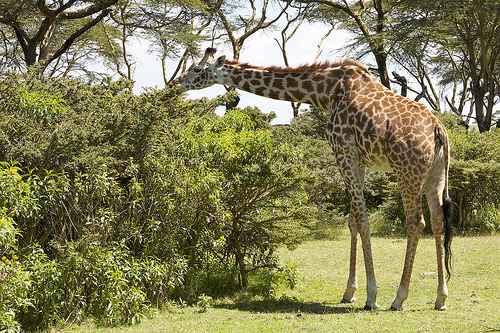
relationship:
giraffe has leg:
[170, 46, 454, 311] [340, 172, 384, 314]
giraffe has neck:
[170, 46, 454, 311] [216, 60, 335, 107]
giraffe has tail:
[170, 46, 454, 311] [435, 123, 456, 283]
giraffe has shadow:
[170, 46, 454, 311] [208, 293, 365, 320]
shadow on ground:
[208, 293, 365, 320] [152, 225, 490, 332]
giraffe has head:
[170, 46, 454, 311] [171, 58, 223, 90]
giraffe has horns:
[170, 46, 454, 311] [198, 46, 218, 60]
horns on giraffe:
[198, 46, 218, 60] [170, 46, 454, 311]